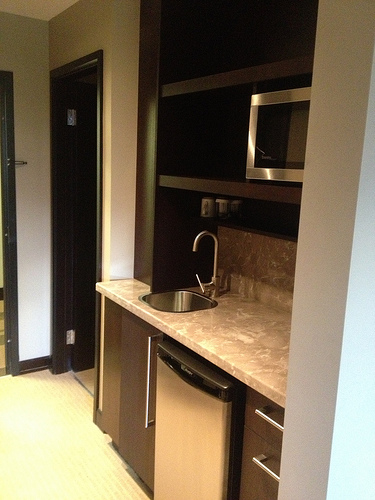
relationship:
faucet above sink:
[192, 230, 221, 300] [137, 284, 215, 312]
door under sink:
[116, 307, 165, 492] [137, 284, 215, 312]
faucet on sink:
[178, 218, 233, 276] [141, 287, 218, 314]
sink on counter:
[138, 289, 219, 316] [97, 277, 289, 403]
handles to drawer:
[247, 408, 282, 488] [235, 391, 281, 498]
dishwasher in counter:
[146, 345, 236, 499] [94, 270, 291, 414]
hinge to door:
[60, 323, 76, 350] [50, 52, 107, 373]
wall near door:
[0, 9, 45, 370] [51, 65, 104, 403]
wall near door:
[0, 9, 45, 370] [0, 71, 23, 375]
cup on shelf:
[197, 199, 249, 216] [191, 206, 295, 241]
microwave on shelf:
[242, 81, 314, 186] [157, 170, 304, 213]